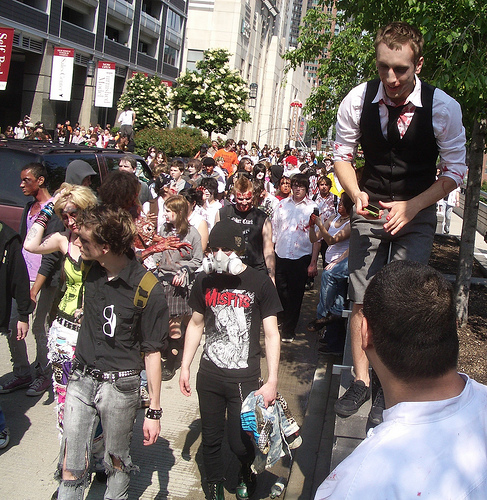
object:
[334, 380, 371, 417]
shoe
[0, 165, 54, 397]
people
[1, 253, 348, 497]
street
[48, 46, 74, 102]
sign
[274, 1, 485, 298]
tree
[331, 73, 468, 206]
shirt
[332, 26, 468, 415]
man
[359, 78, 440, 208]
vest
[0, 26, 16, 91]
banner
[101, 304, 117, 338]
sunglasses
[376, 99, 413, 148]
tie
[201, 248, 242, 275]
mask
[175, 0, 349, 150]
white building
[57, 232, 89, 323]
shirt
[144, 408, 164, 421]
bracelet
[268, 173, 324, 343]
person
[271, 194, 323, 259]
shirt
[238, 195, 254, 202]
sunglasses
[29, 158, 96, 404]
people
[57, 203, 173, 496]
man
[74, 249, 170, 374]
shirt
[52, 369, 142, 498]
jeans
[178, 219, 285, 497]
people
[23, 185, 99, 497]
people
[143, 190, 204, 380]
people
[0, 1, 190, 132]
building